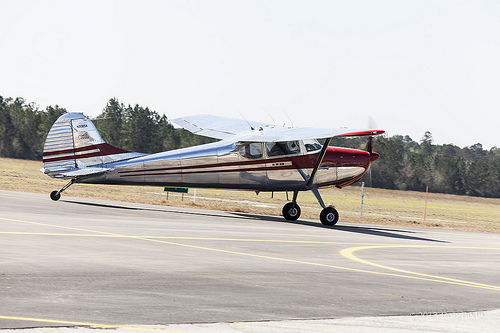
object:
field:
[446, 201, 494, 225]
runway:
[1, 182, 499, 332]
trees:
[387, 125, 499, 198]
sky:
[0, 2, 499, 87]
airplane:
[33, 104, 404, 231]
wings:
[160, 109, 280, 142]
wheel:
[279, 199, 306, 222]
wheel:
[314, 204, 344, 229]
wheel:
[47, 186, 66, 204]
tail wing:
[54, 161, 120, 189]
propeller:
[360, 104, 387, 207]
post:
[419, 186, 431, 223]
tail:
[30, 109, 147, 195]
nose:
[329, 110, 393, 191]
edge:
[0, 305, 499, 332]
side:
[33, 105, 396, 232]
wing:
[233, 117, 393, 156]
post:
[356, 180, 371, 222]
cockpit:
[231, 127, 330, 198]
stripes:
[114, 143, 385, 190]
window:
[233, 137, 264, 162]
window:
[263, 136, 301, 159]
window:
[303, 140, 326, 156]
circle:
[335, 237, 499, 297]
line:
[0, 228, 499, 248]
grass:
[1, 166, 34, 178]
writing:
[270, 160, 291, 168]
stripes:
[35, 141, 136, 166]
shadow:
[50, 193, 455, 249]